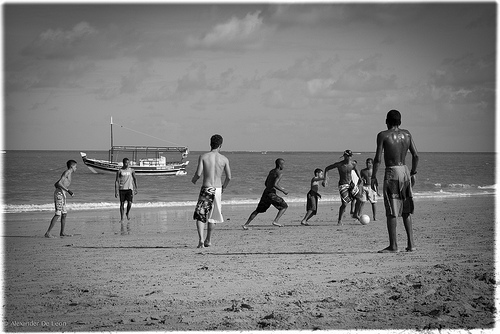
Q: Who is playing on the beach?
A: A group of boys.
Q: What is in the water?
A: A boat.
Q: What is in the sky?
A: Clouds.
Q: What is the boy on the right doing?
A: Watching the others.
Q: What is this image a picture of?
A: A group of boys on the beach playing soccer.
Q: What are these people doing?
A: Playing soccer.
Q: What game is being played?
A: Soccer.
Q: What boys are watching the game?
A: The two closest to the camera.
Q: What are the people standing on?
A: Sandy beach area for people.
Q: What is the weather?
A: A sunny day for playing soccer.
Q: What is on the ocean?
A: A white wave on the ocean.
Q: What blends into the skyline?
A: The water blends into the skyline.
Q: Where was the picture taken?
A: Beach.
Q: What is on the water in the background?
A: Boat.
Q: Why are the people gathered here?
A: Playing soccer.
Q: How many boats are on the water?
A: One.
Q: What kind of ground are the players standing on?
A: Sand.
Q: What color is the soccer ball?
A: White.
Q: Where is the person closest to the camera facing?
A: The shore.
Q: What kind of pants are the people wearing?
A: Shorts.